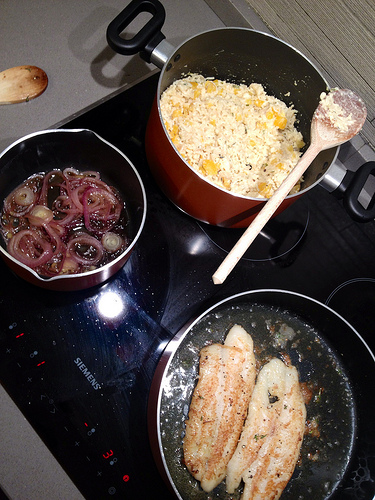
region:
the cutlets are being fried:
[195, 326, 311, 497]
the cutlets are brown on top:
[179, 325, 300, 498]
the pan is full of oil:
[173, 306, 364, 495]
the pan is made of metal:
[149, 279, 372, 499]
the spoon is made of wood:
[205, 90, 364, 276]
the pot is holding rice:
[164, 71, 304, 203]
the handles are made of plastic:
[109, 3, 168, 53]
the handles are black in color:
[108, 3, 170, 56]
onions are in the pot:
[0, 168, 118, 274]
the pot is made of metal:
[2, 121, 145, 304]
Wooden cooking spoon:
[208, 85, 367, 285]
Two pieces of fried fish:
[180, 321, 310, 498]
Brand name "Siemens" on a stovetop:
[70, 353, 100, 389]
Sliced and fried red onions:
[1, 165, 123, 278]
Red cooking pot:
[2, 125, 147, 294]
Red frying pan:
[144, 286, 373, 498]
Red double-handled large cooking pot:
[106, 1, 374, 231]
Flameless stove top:
[3, 63, 371, 498]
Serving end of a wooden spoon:
[1, 63, 48, 103]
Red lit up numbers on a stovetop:
[10, 329, 131, 483]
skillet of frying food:
[138, 283, 374, 495]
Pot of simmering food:
[4, 126, 147, 297]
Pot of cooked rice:
[162, 25, 366, 205]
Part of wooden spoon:
[305, 87, 374, 155]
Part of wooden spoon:
[0, 61, 53, 107]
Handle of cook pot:
[96, 4, 175, 59]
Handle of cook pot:
[324, 165, 373, 222]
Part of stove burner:
[263, 228, 311, 269]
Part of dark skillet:
[248, 284, 317, 332]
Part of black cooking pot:
[85, 137, 123, 175]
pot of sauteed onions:
[26, 203, 66, 229]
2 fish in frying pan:
[208, 347, 302, 454]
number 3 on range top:
[91, 451, 143, 483]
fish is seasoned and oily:
[214, 402, 298, 466]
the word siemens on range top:
[66, 350, 113, 405]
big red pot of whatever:
[192, 182, 249, 241]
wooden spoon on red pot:
[304, 82, 365, 159]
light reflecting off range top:
[94, 304, 126, 322]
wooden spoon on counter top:
[10, 56, 60, 115]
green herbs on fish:
[269, 381, 286, 427]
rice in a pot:
[190, 73, 289, 177]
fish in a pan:
[202, 335, 329, 477]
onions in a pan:
[21, 171, 107, 260]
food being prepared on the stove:
[46, 93, 325, 336]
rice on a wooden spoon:
[322, 97, 352, 133]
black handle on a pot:
[99, 13, 167, 56]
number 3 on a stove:
[96, 445, 121, 462]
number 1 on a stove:
[29, 354, 52, 372]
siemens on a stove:
[65, 350, 106, 395]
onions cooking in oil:
[19, 190, 95, 260]